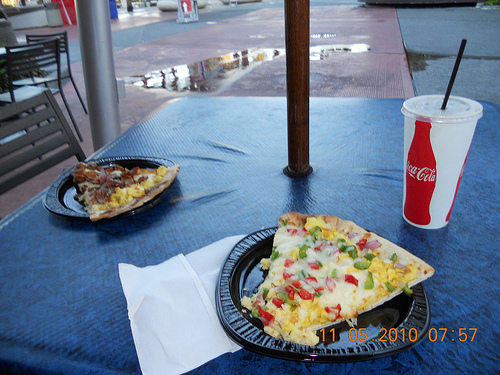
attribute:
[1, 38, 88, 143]
grey chair — metal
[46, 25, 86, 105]
chair — black 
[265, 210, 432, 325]
pizza — large 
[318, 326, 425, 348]
date — orange 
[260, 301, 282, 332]
tomato — red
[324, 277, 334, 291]
tomato — red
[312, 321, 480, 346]
stamp — date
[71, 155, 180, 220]
pizza — slice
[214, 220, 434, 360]
plate — black 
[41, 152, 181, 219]
plate — black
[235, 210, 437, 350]
pizza — slice, large , cheesy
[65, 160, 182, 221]
pizza — cheesy, plastic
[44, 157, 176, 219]
plate — black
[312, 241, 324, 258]
tomato — red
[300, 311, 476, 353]
print — orange, time stamp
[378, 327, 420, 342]
print — orange 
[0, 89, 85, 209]
chair — black 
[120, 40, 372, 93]
puddle — small 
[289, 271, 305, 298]
tomato — red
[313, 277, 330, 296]
tomato — red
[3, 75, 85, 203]
chair — grey